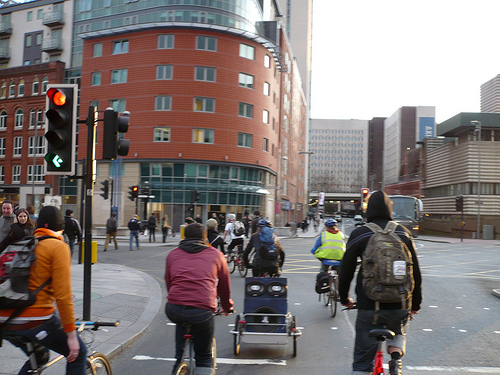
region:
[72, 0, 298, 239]
A curved building.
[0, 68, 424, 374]
A busy road.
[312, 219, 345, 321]
A person riding a bicycle in a safety vest and helment.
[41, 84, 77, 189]
A stop light with turning arrow.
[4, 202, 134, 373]
Person riding bicycle without hands on handlebars.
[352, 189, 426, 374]
Person riding a bicycle with a backpack.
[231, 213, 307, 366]
Person riding a bicycle pulling a cart.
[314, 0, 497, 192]
Bright, clear sky over a city.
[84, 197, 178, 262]
People crossing at an intersection.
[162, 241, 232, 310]
A red jacket.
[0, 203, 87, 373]
the man wearing an orange jacket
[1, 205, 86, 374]
the man wearing blue jeans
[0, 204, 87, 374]
the man riding a bike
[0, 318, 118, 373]
the bike the man is riding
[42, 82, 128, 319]
the traffic lights on a pole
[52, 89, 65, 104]
the red traffic light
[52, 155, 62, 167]
the green arrow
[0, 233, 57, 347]
the backpack and straps on the man's back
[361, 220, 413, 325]
the backpack and straps on the man's back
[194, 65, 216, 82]
the window on the building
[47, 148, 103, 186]
Green arrow illuminated on traffic signal.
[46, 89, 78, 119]
Red light illuminated on traffic signal.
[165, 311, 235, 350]
Person wearing dark jeans.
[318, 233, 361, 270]
Person wearing yellow vest.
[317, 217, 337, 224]
Person wearing helmet on head.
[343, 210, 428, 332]
Person wearing black jacket.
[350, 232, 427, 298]
Back pack on person's back.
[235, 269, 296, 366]
Cart attached to person's bike.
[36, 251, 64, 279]
Person wearing orange shirt.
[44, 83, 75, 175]
traffic light on the left.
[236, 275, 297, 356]
the man is pulling a cart attached to his bike.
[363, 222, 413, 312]
the man has a brown backpack.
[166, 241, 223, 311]
the man is wearing a maroon jacket.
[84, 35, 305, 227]
red curved building in background.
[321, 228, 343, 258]
man wearing bright yellow vest.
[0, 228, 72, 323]
man is wearing orange jacket with gray and black backpack.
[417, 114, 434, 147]
blue sign on building.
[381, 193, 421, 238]
bus in the background.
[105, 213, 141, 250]
two people crossing the street.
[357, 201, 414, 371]
A person riding a bike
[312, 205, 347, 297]
A person riding a bike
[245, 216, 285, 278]
A person riding a bike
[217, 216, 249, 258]
A person riding a bike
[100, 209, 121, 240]
A person crossing a street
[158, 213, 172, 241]
A person crossing a street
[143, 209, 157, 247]
A person crossing a street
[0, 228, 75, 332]
the jacket is orange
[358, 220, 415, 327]
the backpack is military green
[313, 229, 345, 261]
the vest is neon green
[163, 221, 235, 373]
the man riding the bike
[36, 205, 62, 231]
the hat is black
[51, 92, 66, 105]
the light is red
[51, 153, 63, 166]
the arrow is green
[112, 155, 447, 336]
people on the ground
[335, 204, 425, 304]
backpack on the person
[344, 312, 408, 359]
seat on the bike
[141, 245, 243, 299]
back of the person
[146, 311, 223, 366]
legs of the person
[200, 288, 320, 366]
wheels on the ground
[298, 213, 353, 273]
person in green outfit